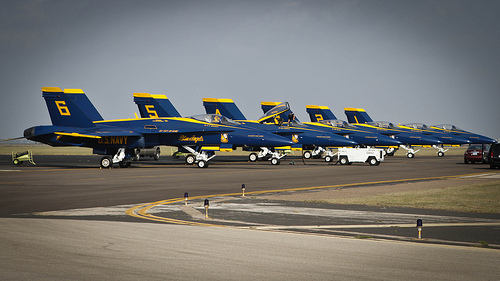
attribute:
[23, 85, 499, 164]
navy jets —  Navy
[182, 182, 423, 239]
lights —  small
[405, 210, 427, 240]
light — for Guide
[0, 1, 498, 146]
sky —  cloudy, hazy, light blue,  grey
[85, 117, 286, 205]
planes —   dark blue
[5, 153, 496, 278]
road — dark gray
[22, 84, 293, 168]
jet —  Navy's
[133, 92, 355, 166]
jet —  Navy's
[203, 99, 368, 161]
jet —  Navy's,  US Navy's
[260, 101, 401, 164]
jet —  Navy's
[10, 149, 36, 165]
item —  Small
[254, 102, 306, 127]
cockpit —  open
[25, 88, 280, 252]
planes —  navy 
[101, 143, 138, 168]
landing gear — white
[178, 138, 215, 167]
landing gear — white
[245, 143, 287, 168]
landing gear — white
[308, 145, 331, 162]
landing gear — white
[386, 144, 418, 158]
landing gear — white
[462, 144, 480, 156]
landing gear — white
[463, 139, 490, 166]
vehicle —  red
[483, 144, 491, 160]
door —  ajar 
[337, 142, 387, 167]
servicing vehicle —   Small, for aircraft servicing 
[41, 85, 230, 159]
jet — yellow, blue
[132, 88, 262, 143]
jet — yellow, blue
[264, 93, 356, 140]
jet — yellow, blue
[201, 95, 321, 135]
jet — yellow, blue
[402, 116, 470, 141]
jet — yellow, blue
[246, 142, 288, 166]
landing gear — plane,  for landing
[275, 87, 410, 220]
truck —  white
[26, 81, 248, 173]
jet —  US Navy's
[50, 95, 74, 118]
number —  yellow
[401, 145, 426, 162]
landing gear —  for landing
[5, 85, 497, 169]
jets —  of US Navy,  in A row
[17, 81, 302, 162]
jet —  US Navy's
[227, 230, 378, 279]
road — light gray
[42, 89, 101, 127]
tail —  plane's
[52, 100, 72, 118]
number —  yellow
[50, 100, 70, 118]
numbers —  yellow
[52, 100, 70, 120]
6 —  numeral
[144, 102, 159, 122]
5 —  number